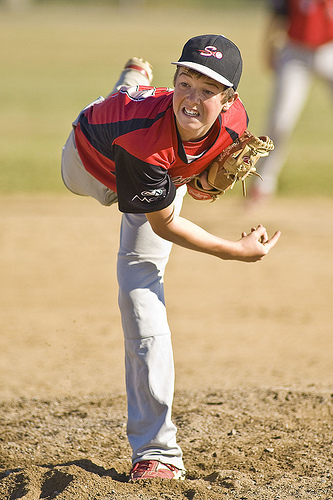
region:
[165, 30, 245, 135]
the head of a boy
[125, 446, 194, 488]
a red shoe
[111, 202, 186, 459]
the leg of a boy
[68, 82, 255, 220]
a red and black tee shirt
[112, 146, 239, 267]
the arm of a boy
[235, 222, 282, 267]
the hand of a boy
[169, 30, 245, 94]
a black and gray baseball cap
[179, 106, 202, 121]
the mouth of a boy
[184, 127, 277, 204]
a brown baseball mitt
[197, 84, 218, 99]
the eye of a boy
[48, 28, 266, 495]
little boy standing on the pitcher's mound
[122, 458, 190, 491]
red and white baseball spikes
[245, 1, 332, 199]
player standing in the infield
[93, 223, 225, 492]
only one leg on the ground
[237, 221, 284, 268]
pointer finger sticking out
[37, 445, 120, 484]
shadow on the dirt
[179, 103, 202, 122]
mouth open, showing teeth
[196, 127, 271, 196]
tan baseball glove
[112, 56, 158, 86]
foot kicked back in the air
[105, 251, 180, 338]
knee slightly bent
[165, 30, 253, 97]
a black and white hat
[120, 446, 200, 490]
red and white athletic shoe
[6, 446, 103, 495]
a pile of dirt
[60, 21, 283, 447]
a boy playing baseball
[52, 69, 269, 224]
a red and black jersey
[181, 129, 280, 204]
a brown leather mit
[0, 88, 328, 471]
a baseball field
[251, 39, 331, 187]
a light colored pair of pants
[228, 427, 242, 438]
small rock in the dirt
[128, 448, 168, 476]
bright red shoe laces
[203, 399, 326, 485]
Ground is brown color.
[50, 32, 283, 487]
Boy is throwing the ball.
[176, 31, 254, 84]
Cap is black color.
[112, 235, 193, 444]
Boy is white color.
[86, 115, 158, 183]
Shirt is red and black color.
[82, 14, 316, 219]
Two players are in ground.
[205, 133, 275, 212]
Gloves are brown color.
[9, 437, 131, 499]
Shadow falls on ground.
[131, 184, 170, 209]
Letters are white color.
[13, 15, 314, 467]
Day time picture.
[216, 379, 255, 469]
The ground is brown,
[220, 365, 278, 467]
The ground is brown,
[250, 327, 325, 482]
The ground is brown,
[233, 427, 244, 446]
The ground is brown,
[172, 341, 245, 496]
The ground is brown,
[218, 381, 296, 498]
The ground is brown,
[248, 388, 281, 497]
The ground is brown,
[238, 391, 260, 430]
The ground is brown,